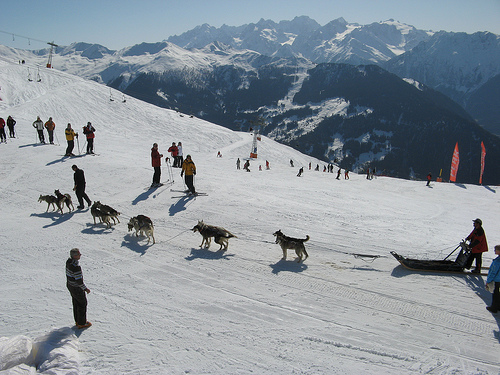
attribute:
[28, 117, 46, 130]
top — white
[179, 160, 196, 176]
jacket — yellow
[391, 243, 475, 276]
sled — dark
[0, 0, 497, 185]
mountains — tree-covered, rocky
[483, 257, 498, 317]
jacket — blue